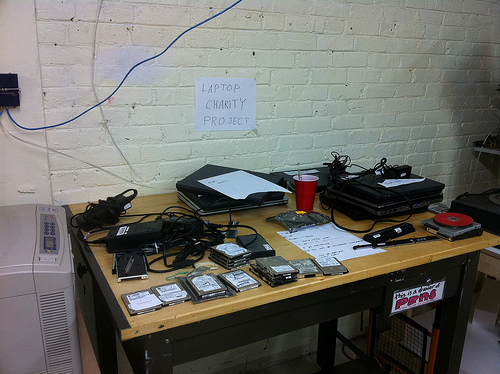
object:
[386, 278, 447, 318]
label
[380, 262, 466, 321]
drawer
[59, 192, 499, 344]
table top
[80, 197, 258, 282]
drives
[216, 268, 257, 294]
disk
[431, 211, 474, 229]
disk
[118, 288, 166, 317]
disk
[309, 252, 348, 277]
disk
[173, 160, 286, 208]
laptop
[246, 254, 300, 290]
disk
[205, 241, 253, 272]
disk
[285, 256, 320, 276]
disk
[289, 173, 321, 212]
cup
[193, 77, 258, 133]
sign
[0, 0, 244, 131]
cord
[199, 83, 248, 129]
text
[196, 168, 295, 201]
cd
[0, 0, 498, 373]
wall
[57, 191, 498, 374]
desk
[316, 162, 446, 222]
computers